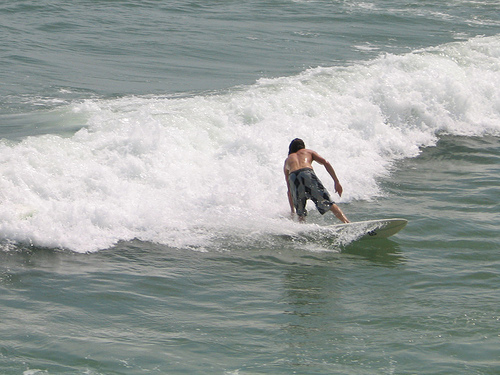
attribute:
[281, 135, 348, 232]
man — surfing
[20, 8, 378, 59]
water — rolling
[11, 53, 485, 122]
waves — nice, awesome, good, strong, white, gray, grey, whtie